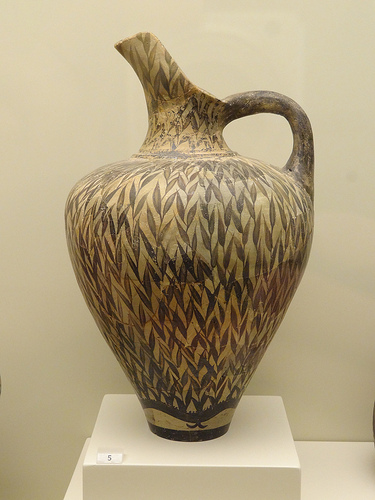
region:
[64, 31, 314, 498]
an artifact in a museum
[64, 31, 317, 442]
a brown and yellow pitcher on display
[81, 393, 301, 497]
a white display stand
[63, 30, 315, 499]
a pitcher on a white display stand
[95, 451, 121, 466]
number 5 on the artifact's display stand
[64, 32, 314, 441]
an ancient brown and yellow pitcher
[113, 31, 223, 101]
the spout on a pitcher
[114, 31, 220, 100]
a spout to pour water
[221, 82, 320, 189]
the handle near the spout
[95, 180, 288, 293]
design of leaves on the ancient pitcher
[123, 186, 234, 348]
brown leaves pattern on jar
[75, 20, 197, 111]
top part of pot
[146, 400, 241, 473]
base of the pot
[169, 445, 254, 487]
stand for the pot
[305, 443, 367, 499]
area next to pot stand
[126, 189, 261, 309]
brown pot with design on it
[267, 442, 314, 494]
edge of the stand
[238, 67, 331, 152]
handle of the pot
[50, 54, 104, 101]
wall behind the pot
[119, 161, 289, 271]
fat part of pot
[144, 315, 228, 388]
leaf design on pot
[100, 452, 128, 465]
The exhibit's number is 5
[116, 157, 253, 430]
A vase with a leaf pattern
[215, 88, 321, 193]
The handle of the vase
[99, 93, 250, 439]
A bronze colored vase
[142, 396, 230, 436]
The brown trim of the vase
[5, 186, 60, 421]
A white wall behind the vase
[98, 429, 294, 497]
A white pedestal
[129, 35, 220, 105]
The mouth of the vase is chipped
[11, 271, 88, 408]
A blank wall behind the vase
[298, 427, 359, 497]
A white desk beneath the vase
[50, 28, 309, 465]
The vase is tall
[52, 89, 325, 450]
The vase has a small base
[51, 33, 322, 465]
The vase is beige and black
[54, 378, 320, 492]
White block under the vase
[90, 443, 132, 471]
Number 5 on tag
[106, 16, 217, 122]
Vase has a curved lip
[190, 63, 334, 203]
Vase has a short handle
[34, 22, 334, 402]
Vase has a pattern of leaves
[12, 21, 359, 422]
Wall behind base is white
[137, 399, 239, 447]
Bottom of vase is black